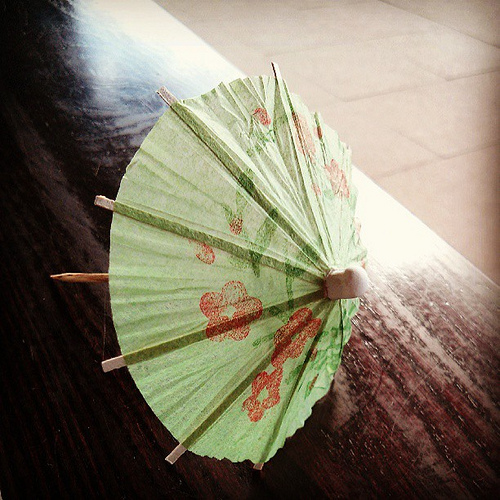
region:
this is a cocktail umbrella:
[98, 81, 367, 421]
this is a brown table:
[373, 262, 465, 467]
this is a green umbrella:
[162, 239, 319, 446]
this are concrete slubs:
[316, 31, 497, 233]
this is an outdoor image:
[29, 27, 394, 416]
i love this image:
[91, 236, 370, 452]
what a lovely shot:
[16, 24, 251, 223]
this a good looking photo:
[13, 276, 168, 488]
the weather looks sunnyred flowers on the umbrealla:
[176, 257, 282, 342]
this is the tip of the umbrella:
[311, 256, 368, 295]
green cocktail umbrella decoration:
[125, 75, 262, 341]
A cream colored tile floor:
[345, 22, 432, 183]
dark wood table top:
[375, 235, 445, 431]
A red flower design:
[190, 235, 265, 355]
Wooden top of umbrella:
[300, 240, 390, 335]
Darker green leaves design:
[220, 160, 321, 275]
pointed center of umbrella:
[31, 211, 197, 301]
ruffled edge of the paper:
[155, 422, 315, 477]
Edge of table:
[150, 0, 250, 76]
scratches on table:
[351, 300, 430, 460]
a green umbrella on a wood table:
[9, 60, 497, 496]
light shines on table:
[385, 240, 475, 372]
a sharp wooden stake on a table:
[31, 266, 115, 292]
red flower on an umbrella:
[202, 274, 288, 347]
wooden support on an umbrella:
[96, 343, 133, 378]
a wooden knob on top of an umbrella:
[331, 254, 384, 312]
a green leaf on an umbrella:
[249, 210, 304, 274]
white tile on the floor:
[347, 37, 470, 136]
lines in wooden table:
[34, 423, 124, 486]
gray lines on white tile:
[377, 158, 447, 177]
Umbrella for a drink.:
[52, 101, 382, 425]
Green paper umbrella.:
[142, 268, 242, 430]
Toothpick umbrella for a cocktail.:
[59, 235, 486, 316]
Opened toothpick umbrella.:
[70, 198, 405, 374]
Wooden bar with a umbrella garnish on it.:
[333, 365, 419, 431]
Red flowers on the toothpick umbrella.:
[182, 256, 318, 376]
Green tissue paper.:
[151, 197, 371, 413]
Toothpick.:
[33, 257, 125, 304]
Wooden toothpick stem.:
[40, 245, 105, 300]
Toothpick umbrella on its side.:
[35, 202, 430, 411]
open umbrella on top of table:
[40, 52, 421, 450]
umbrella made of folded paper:
[91, 50, 398, 475]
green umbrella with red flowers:
[85, 60, 401, 475]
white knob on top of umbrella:
[290, 226, 375, 311]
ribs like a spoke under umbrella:
[85, 55, 420, 472]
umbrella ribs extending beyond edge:
[90, 347, 195, 484]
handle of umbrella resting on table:
[45, 265, 236, 305]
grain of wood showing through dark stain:
[365, 251, 475, 476]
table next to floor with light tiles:
[355, 30, 480, 280]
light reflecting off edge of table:
[342, 152, 452, 295]